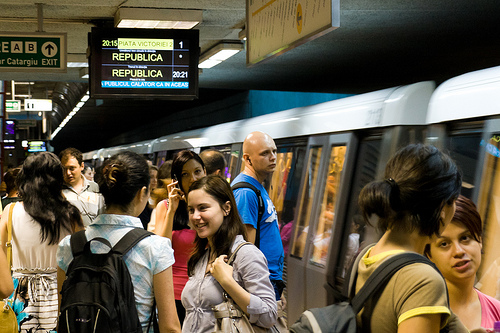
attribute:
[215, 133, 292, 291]
man — shaved, bald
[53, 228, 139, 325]
backpack — black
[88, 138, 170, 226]
hair — dark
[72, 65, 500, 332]
train — white, grey, waiting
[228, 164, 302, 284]
shirt — blue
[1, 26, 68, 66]
sign — green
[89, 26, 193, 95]
monitor — black, hanging, overhead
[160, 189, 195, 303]
shirt — pink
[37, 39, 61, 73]
exit — overhead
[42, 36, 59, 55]
circle — white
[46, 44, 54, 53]
arrow — green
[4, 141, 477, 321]
people — waiting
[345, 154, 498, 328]
women — talking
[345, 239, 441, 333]
shirt — yellow